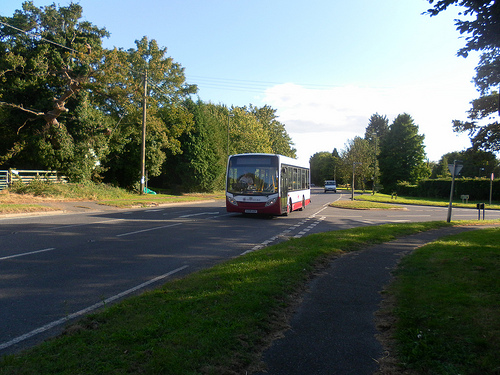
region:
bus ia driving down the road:
[202, 129, 324, 253]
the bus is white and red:
[192, 148, 325, 217]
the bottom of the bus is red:
[232, 191, 337, 218]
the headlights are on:
[209, 185, 280, 216]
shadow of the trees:
[5, 200, 310, 303]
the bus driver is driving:
[201, 148, 283, 203]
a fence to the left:
[10, 150, 107, 212]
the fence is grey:
[4, 165, 91, 207]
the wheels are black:
[270, 189, 315, 217]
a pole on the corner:
[430, 147, 463, 228]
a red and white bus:
[219, 147, 315, 217]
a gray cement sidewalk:
[244, 212, 494, 367]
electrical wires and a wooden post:
[121, 59, 237, 197]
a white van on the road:
[308, 172, 344, 196]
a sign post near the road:
[428, 147, 458, 228]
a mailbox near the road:
[473, 194, 488, 226]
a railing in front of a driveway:
[1, 162, 116, 220]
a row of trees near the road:
[14, 7, 323, 193]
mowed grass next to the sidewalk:
[363, 238, 408, 372]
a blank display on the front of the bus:
[229, 154, 280, 211]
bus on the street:
[224, 145, 339, 221]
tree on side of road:
[348, 137, 378, 194]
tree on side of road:
[385, 111, 421, 188]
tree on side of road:
[364, 110, 390, 149]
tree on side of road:
[138, 127, 163, 202]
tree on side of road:
[191, 101, 211, 191]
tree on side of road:
[200, 99, 230, 191]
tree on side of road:
[120, 38, 178, 187]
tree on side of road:
[51, 28, 114, 192]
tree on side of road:
[0, 19, 55, 181]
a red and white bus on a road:
[58, 151, 315, 294]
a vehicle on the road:
[317, 170, 343, 200]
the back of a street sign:
[436, 158, 463, 228]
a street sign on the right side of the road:
[483, 166, 496, 209]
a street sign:
[343, 161, 362, 203]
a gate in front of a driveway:
[2, 166, 114, 212]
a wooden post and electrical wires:
[56, 39, 228, 199]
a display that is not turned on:
[225, 154, 278, 215]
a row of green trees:
[18, 46, 278, 191]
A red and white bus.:
[222, 145, 314, 219]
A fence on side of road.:
[3, 165, 72, 189]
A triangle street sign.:
[445, 159, 469, 181]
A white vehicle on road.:
[322, 178, 339, 195]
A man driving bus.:
[235, 170, 252, 186]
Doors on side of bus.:
[278, 165, 290, 212]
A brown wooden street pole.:
[138, 65, 148, 195]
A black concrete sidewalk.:
[268, 232, 400, 373]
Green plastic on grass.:
[140, 183, 155, 198]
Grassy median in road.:
[327, 194, 403, 211]